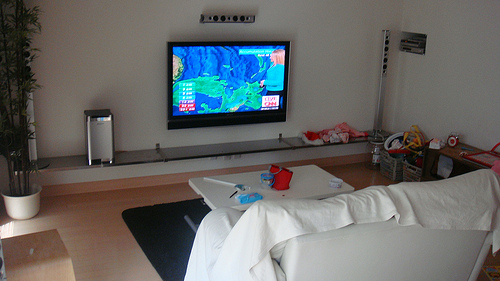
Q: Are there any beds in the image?
A: No, there are no beds.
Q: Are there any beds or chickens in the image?
A: No, there are no beds or chickens.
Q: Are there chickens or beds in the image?
A: No, there are no beds or chickens.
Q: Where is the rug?
A: The rug is on the floor.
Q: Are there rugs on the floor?
A: Yes, there is a rug on the floor.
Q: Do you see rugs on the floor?
A: Yes, there is a rug on the floor.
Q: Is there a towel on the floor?
A: No, there is a rug on the floor.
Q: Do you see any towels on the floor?
A: No, there is a rug on the floor.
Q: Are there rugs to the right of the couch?
A: No, the rug is to the left of the couch.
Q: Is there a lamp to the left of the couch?
A: No, there is a rug to the left of the couch.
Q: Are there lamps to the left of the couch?
A: No, there is a rug to the left of the couch.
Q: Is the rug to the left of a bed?
A: No, the rug is to the left of a couch.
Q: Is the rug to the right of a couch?
A: No, the rug is to the left of a couch.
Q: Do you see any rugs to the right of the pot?
A: Yes, there is a rug to the right of the pot.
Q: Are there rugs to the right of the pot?
A: Yes, there is a rug to the right of the pot.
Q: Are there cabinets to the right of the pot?
A: No, there is a rug to the right of the pot.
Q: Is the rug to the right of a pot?
A: Yes, the rug is to the right of a pot.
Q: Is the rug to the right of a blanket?
A: No, the rug is to the right of a pot.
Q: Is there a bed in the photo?
A: No, there are no beds.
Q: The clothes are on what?
A: The clothes are on the shelf.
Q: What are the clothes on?
A: The clothes are on the shelf.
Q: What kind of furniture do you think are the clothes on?
A: The clothes are on the shelf.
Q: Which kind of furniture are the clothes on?
A: The clothes are on the shelf.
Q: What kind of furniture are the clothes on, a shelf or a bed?
A: The clothes are on a shelf.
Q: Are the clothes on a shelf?
A: Yes, the clothes are on a shelf.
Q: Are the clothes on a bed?
A: No, the clothes are on a shelf.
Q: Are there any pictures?
A: No, there are no pictures.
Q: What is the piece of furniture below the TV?
A: The piece of furniture is a shelf.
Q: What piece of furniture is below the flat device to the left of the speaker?
A: The piece of furniture is a shelf.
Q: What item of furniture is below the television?
A: The piece of furniture is a shelf.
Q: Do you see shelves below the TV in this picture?
A: Yes, there is a shelf below the TV.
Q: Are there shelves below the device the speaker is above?
A: Yes, there is a shelf below the TV.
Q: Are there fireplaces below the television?
A: No, there is a shelf below the television.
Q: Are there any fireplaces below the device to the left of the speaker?
A: No, there is a shelf below the television.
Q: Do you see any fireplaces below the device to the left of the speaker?
A: No, there is a shelf below the television.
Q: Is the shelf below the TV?
A: Yes, the shelf is below the TV.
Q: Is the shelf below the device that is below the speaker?
A: Yes, the shelf is below the TV.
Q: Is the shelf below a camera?
A: No, the shelf is below the TV.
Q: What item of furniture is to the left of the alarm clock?
A: The piece of furniture is a shelf.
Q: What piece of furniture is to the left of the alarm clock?
A: The piece of furniture is a shelf.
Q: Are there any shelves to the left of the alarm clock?
A: Yes, there is a shelf to the left of the alarm clock.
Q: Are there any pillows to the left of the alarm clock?
A: No, there is a shelf to the left of the alarm clock.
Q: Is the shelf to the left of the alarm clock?
A: Yes, the shelf is to the left of the alarm clock.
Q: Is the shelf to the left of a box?
A: No, the shelf is to the left of the alarm clock.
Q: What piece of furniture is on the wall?
A: The piece of furniture is a shelf.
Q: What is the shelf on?
A: The shelf is on the wall.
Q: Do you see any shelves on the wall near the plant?
A: Yes, there is a shelf on the wall.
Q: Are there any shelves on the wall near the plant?
A: Yes, there is a shelf on the wall.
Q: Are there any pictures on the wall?
A: No, there is a shelf on the wall.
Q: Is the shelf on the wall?
A: Yes, the shelf is on the wall.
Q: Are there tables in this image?
A: Yes, there is a table.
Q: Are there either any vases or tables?
A: Yes, there is a table.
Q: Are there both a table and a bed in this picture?
A: No, there is a table but no beds.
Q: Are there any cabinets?
A: No, there are no cabinets.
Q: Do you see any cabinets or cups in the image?
A: No, there are no cabinets or cups.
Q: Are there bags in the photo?
A: Yes, there is a bag.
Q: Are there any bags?
A: Yes, there is a bag.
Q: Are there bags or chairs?
A: Yes, there is a bag.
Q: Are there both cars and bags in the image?
A: No, there is a bag but no cars.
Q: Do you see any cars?
A: No, there are no cars.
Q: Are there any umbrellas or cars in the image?
A: No, there are no cars or umbrellas.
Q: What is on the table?
A: The bag is on the table.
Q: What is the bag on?
A: The bag is on the table.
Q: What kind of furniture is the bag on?
A: The bag is on the table.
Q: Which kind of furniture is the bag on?
A: The bag is on the table.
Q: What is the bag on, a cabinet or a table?
A: The bag is on a table.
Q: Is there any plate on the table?
A: No, there is a bag on the table.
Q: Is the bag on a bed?
A: No, the bag is on the table.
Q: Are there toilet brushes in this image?
A: No, there are no toilet brushes.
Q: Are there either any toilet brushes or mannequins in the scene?
A: No, there are no toilet brushes or mannequins.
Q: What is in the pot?
A: The plant is in the pot.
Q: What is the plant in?
A: The plant is in the pot.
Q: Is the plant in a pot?
A: Yes, the plant is in a pot.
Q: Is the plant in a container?
A: No, the plant is in a pot.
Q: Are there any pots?
A: Yes, there is a pot.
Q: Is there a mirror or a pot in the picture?
A: Yes, there is a pot.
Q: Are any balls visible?
A: No, there are no balls.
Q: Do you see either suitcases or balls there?
A: No, there are no balls or suitcases.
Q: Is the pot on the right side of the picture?
A: No, the pot is on the left of the image.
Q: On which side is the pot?
A: The pot is on the left of the image.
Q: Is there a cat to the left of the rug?
A: No, there is a pot to the left of the rug.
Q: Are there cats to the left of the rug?
A: No, there is a pot to the left of the rug.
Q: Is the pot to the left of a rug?
A: Yes, the pot is to the left of a rug.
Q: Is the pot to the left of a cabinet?
A: No, the pot is to the left of a rug.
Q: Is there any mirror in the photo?
A: No, there are no mirrors.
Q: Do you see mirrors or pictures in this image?
A: No, there are no mirrors or pictures.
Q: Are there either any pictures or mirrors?
A: No, there are no mirrors or pictures.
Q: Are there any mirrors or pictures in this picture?
A: No, there are no mirrors or pictures.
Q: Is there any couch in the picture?
A: Yes, there is a couch.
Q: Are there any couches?
A: Yes, there is a couch.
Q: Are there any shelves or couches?
A: Yes, there is a couch.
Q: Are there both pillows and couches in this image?
A: No, there is a couch but no pillows.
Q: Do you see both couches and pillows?
A: No, there is a couch but no pillows.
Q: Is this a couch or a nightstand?
A: This is a couch.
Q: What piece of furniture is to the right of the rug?
A: The piece of furniture is a couch.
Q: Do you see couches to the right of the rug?
A: Yes, there is a couch to the right of the rug.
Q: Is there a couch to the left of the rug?
A: No, the couch is to the right of the rug.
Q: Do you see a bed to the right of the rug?
A: No, there is a couch to the right of the rug.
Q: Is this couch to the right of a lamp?
A: No, the couch is to the right of the rug.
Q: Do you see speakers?
A: Yes, there is a speaker.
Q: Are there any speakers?
A: Yes, there is a speaker.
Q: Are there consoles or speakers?
A: Yes, there is a speaker.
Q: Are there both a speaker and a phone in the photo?
A: No, there is a speaker but no phones.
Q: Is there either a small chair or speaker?
A: Yes, there is a small speaker.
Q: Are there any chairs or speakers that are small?
A: Yes, the speaker is small.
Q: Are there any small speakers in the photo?
A: Yes, there is a small speaker.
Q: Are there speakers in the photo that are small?
A: Yes, there is a speaker that is small.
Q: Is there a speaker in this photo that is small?
A: Yes, there is a speaker that is small.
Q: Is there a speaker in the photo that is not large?
A: Yes, there is a small speaker.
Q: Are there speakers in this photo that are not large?
A: Yes, there is a small speaker.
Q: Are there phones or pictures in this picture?
A: No, there are no pictures or phones.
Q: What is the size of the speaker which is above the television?
A: The speaker is small.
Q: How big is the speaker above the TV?
A: The speaker is small.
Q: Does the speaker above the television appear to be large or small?
A: The speaker is small.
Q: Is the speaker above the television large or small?
A: The speaker is small.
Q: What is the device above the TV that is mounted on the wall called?
A: The device is a speaker.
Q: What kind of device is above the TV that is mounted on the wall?
A: The device is a speaker.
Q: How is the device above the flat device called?
A: The device is a speaker.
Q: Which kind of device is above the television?
A: The device is a speaker.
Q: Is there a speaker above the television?
A: Yes, there is a speaker above the television.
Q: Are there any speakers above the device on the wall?
A: Yes, there is a speaker above the television.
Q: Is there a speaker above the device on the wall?
A: Yes, there is a speaker above the television.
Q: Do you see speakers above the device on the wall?
A: Yes, there is a speaker above the television.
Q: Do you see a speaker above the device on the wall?
A: Yes, there is a speaker above the television.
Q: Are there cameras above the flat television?
A: No, there is a speaker above the TV.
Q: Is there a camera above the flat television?
A: No, there is a speaker above the TV.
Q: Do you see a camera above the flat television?
A: No, there is a speaker above the TV.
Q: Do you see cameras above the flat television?
A: No, there is a speaker above the TV.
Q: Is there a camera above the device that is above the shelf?
A: No, there is a speaker above the TV.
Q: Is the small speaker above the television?
A: Yes, the speaker is above the television.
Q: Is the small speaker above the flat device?
A: Yes, the speaker is above the television.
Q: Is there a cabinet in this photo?
A: No, there are no cabinets.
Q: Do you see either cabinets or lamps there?
A: No, there are no cabinets or lamps.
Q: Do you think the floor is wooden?
A: Yes, the floor is wooden.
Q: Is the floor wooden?
A: Yes, the floor is wooden.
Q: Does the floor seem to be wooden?
A: Yes, the floor is wooden.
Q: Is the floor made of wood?
A: Yes, the floor is made of wood.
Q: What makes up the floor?
A: The floor is made of wood.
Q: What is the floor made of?
A: The floor is made of wood.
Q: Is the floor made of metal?
A: No, the floor is made of wood.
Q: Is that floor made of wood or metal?
A: The floor is made of wood.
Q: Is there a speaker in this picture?
A: Yes, there is a speaker.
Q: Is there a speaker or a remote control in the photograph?
A: Yes, there is a speaker.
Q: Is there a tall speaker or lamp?
A: Yes, there is a tall speaker.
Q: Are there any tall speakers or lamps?
A: Yes, there is a tall speaker.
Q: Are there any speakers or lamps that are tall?
A: Yes, the speaker is tall.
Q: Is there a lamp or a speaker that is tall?
A: Yes, the speaker is tall.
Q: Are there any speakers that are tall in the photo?
A: Yes, there is a tall speaker.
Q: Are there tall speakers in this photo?
A: Yes, there is a tall speaker.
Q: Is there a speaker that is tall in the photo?
A: Yes, there is a tall speaker.